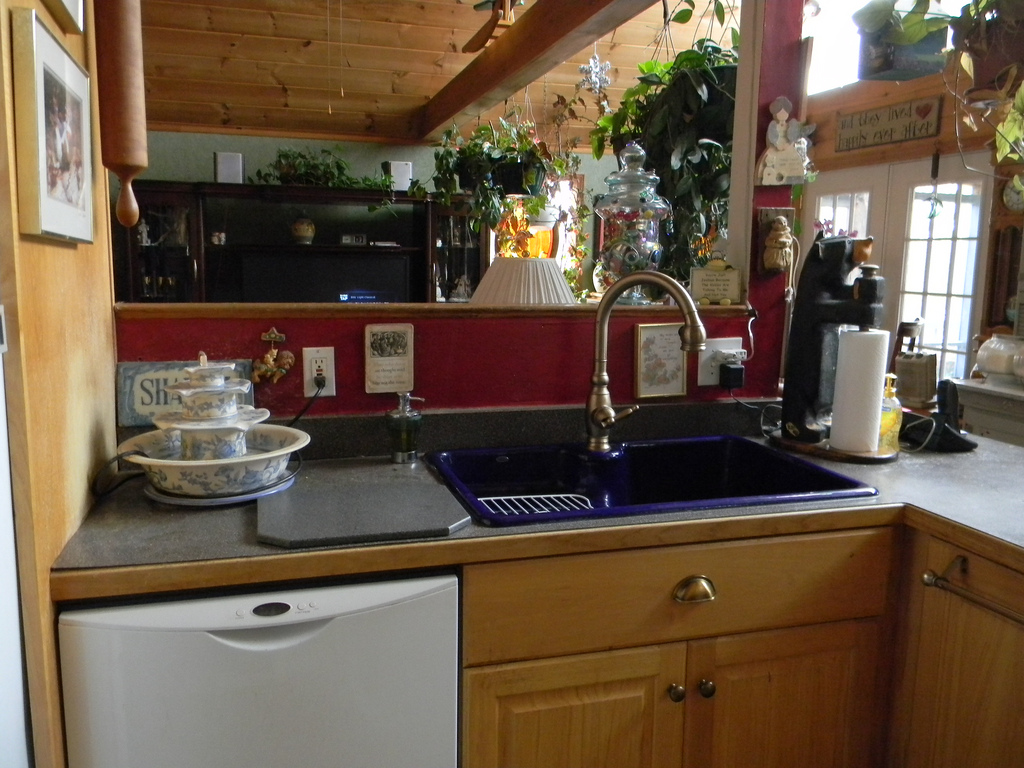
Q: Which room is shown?
A: It is a kitchen.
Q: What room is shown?
A: It is a kitchen.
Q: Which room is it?
A: It is a kitchen.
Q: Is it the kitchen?
A: Yes, it is the kitchen.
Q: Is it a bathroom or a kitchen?
A: It is a kitchen.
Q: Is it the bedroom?
A: No, it is the kitchen.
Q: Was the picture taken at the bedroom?
A: No, the picture was taken in the kitchen.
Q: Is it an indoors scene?
A: Yes, it is indoors.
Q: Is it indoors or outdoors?
A: It is indoors.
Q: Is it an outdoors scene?
A: No, it is indoors.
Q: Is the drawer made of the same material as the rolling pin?
A: Yes, both the drawer and the rolling pin are made of wood.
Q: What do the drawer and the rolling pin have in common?
A: The material, both the drawer and the rolling pin are wooden.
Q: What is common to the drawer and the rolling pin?
A: The material, both the drawer and the rolling pin are wooden.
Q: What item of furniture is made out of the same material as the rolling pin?
A: The drawer is made of the same material as the rolling pin.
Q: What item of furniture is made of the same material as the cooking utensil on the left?
A: The drawer is made of the same material as the rolling pin.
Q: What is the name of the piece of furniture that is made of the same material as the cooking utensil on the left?
A: The piece of furniture is a drawer.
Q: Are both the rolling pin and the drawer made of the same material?
A: Yes, both the rolling pin and the drawer are made of wood.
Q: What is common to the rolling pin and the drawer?
A: The material, both the rolling pin and the drawer are wooden.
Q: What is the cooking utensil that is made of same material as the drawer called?
A: The cooking utensil is a rolling pin.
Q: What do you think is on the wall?
A: The electrical outlet is on the wall.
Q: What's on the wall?
A: The electrical outlet is on the wall.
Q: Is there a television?
A: Yes, there is a television.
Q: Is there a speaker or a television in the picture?
A: Yes, there is a television.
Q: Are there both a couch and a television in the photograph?
A: No, there is a television but no couches.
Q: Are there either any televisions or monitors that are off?
A: Yes, the television is off.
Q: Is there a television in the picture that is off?
A: Yes, there is a television that is off.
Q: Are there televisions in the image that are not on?
A: Yes, there is a television that is off.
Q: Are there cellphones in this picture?
A: No, there are no cellphones.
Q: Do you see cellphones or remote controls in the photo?
A: No, there are no cellphones or remote controls.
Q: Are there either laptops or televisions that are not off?
A: No, there is a television but it is off.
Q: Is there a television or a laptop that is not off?
A: No, there is a television but it is off.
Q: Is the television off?
A: Yes, the television is off.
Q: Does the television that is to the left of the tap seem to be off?
A: Yes, the TV is off.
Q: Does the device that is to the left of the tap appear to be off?
A: Yes, the TV is off.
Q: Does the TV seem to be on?
A: No, the TV is off.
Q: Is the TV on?
A: No, the TV is off.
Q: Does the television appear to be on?
A: No, the television is off.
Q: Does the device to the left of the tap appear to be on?
A: No, the television is off.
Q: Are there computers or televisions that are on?
A: No, there is a television but it is off.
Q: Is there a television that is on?
A: No, there is a television but it is off.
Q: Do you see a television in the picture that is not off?
A: No, there is a television but it is off.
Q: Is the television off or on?
A: The television is off.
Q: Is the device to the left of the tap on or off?
A: The television is off.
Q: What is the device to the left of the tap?
A: The device is a television.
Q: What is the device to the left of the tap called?
A: The device is a television.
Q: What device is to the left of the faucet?
A: The device is a television.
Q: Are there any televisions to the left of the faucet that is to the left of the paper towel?
A: Yes, there is a television to the left of the faucet.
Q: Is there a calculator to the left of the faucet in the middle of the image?
A: No, there is a television to the left of the tap.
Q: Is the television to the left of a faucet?
A: Yes, the television is to the left of a faucet.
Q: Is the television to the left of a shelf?
A: No, the television is to the left of a faucet.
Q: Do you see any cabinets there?
A: Yes, there is a cabinet.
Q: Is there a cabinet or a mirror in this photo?
A: Yes, there is a cabinet.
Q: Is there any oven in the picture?
A: No, there are no ovens.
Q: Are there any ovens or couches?
A: No, there are no ovens or couches.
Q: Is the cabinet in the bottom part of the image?
A: Yes, the cabinet is in the bottom of the image.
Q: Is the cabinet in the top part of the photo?
A: No, the cabinet is in the bottom of the image.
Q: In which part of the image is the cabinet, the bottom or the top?
A: The cabinet is in the bottom of the image.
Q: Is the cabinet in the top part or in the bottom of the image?
A: The cabinet is in the bottom of the image.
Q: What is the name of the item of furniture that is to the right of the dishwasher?
A: The piece of furniture is a cabinet.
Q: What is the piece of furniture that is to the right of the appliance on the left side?
A: The piece of furniture is a cabinet.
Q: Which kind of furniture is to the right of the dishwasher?
A: The piece of furniture is a cabinet.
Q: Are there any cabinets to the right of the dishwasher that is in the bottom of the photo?
A: Yes, there is a cabinet to the right of the dishwasher.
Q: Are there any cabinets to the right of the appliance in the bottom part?
A: Yes, there is a cabinet to the right of the dishwasher.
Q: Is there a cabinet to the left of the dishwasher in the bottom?
A: No, the cabinet is to the right of the dishwasher.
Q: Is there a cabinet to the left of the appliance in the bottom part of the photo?
A: No, the cabinet is to the right of the dishwasher.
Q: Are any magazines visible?
A: No, there are no magazines.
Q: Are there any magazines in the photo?
A: No, there are no magazines.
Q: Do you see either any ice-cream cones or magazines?
A: No, there are no magazines or ice-cream cones.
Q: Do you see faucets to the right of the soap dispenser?
A: Yes, there is a faucet to the right of the soap dispenser.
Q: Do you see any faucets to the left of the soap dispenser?
A: No, the faucet is to the right of the soap dispenser.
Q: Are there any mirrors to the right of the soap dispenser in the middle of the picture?
A: No, there is a faucet to the right of the soap dispenser.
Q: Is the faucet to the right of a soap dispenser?
A: Yes, the faucet is to the right of a soap dispenser.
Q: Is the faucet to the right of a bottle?
A: No, the faucet is to the right of a soap dispenser.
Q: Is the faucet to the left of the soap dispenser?
A: No, the faucet is to the right of the soap dispenser.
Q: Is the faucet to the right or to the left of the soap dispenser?
A: The faucet is to the right of the soap dispenser.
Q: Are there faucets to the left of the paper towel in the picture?
A: Yes, there is a faucet to the left of the paper towel.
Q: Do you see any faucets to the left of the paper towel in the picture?
A: Yes, there is a faucet to the left of the paper towel.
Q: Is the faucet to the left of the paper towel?
A: Yes, the faucet is to the left of the paper towel.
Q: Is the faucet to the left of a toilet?
A: No, the faucet is to the left of the paper towel.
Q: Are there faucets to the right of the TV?
A: Yes, there is a faucet to the right of the TV.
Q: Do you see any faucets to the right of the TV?
A: Yes, there is a faucet to the right of the TV.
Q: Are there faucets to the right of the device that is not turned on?
A: Yes, there is a faucet to the right of the TV.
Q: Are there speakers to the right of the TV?
A: No, there is a faucet to the right of the TV.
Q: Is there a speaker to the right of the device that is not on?
A: No, there is a faucet to the right of the TV.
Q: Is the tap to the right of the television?
A: Yes, the tap is to the right of the television.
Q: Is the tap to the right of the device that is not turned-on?
A: Yes, the tap is to the right of the television.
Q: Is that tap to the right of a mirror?
A: No, the tap is to the right of the television.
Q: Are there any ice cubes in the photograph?
A: No, there are no ice cubes.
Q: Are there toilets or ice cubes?
A: No, there are no ice cubes or toilets.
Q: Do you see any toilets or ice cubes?
A: No, there are no ice cubes or toilets.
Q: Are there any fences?
A: No, there are no fences.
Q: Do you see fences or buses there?
A: No, there are no fences or buses.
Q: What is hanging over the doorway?
A: The sign is hanging over the doorway.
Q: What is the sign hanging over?
A: The sign is hanging over the doorway.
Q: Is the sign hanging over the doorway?
A: Yes, the sign is hanging over the doorway.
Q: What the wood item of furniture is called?
A: The piece of furniture is a drawer.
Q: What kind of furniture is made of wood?
A: The furniture is a drawer.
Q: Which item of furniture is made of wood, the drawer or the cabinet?
A: The drawer is made of wood.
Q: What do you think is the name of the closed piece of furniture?
A: The piece of furniture is a drawer.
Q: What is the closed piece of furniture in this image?
A: The piece of furniture is a drawer.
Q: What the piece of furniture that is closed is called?
A: The piece of furniture is a drawer.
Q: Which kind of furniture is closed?
A: The furniture is a drawer.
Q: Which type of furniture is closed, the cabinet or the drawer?
A: The drawer is closed.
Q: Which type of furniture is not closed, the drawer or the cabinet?
A: The cabinet is not closed.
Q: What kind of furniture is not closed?
A: The furniture is a cabinet.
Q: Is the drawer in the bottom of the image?
A: Yes, the drawer is in the bottom of the image.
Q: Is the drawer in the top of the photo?
A: No, the drawer is in the bottom of the image.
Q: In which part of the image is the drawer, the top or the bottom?
A: The drawer is in the bottom of the image.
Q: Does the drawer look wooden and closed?
A: Yes, the drawer is wooden and closed.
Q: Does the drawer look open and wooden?
A: No, the drawer is wooden but closed.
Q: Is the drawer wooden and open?
A: No, the drawer is wooden but closed.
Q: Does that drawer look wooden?
A: Yes, the drawer is wooden.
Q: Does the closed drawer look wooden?
A: Yes, the drawer is wooden.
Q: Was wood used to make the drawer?
A: Yes, the drawer is made of wood.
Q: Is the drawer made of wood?
A: Yes, the drawer is made of wood.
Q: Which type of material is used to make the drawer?
A: The drawer is made of wood.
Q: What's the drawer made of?
A: The drawer is made of wood.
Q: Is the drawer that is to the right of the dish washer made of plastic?
A: No, the drawer is made of wood.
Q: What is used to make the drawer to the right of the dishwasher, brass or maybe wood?
A: The drawer is made of wood.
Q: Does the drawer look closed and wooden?
A: Yes, the drawer is closed and wooden.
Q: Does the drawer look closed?
A: Yes, the drawer is closed.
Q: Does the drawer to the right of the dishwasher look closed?
A: Yes, the drawer is closed.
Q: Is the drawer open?
A: No, the drawer is closed.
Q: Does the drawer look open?
A: No, the drawer is closed.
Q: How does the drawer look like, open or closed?
A: The drawer is closed.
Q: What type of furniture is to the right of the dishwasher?
A: The piece of furniture is a drawer.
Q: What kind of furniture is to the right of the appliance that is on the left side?
A: The piece of furniture is a drawer.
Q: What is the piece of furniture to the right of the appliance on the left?
A: The piece of furniture is a drawer.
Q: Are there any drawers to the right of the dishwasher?
A: Yes, there is a drawer to the right of the dishwasher.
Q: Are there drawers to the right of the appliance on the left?
A: Yes, there is a drawer to the right of the dishwasher.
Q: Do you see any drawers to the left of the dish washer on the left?
A: No, the drawer is to the right of the dishwasher.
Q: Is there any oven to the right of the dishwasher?
A: No, there is a drawer to the right of the dishwasher.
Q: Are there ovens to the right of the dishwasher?
A: No, there is a drawer to the right of the dishwasher.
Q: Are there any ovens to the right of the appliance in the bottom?
A: No, there is a drawer to the right of the dishwasher.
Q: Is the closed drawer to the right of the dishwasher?
A: Yes, the drawer is to the right of the dishwasher.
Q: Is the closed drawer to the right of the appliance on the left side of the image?
A: Yes, the drawer is to the right of the dishwasher.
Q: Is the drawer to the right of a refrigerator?
A: No, the drawer is to the right of the dishwasher.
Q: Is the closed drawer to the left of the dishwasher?
A: No, the drawer is to the right of the dishwasher.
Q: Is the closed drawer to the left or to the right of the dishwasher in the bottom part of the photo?
A: The drawer is to the right of the dishwasher.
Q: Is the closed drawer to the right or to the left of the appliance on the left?
A: The drawer is to the right of the dishwasher.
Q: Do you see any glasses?
A: No, there are no glasses.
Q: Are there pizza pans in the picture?
A: No, there are no pizza pans.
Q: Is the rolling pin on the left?
A: Yes, the rolling pin is on the left of the image.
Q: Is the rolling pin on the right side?
A: No, the rolling pin is on the left of the image.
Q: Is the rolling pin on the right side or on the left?
A: The rolling pin is on the left of the image.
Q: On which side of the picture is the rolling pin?
A: The rolling pin is on the left of the image.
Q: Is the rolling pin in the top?
A: Yes, the rolling pin is in the top of the image.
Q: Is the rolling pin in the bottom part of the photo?
A: No, the rolling pin is in the top of the image.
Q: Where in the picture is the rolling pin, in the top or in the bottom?
A: The rolling pin is in the top of the image.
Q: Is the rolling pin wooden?
A: Yes, the rolling pin is wooden.